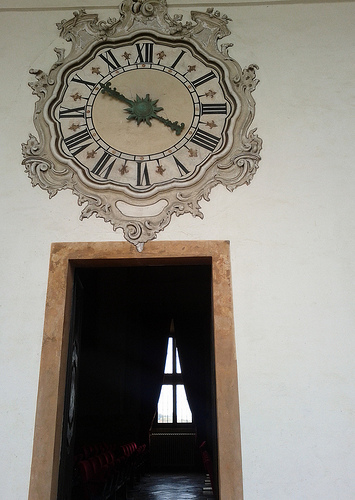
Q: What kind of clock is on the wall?
A: A clock with roman numerals.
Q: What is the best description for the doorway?
A: It is made out of beige marble.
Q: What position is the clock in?
A: Hanging over the doorway.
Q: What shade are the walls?
A: White.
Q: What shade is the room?
A: The inside of the room is dark.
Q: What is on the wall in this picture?
A: A clock.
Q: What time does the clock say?
A: 3:51.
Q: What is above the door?
A: Clock.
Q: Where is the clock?
A: Above the door.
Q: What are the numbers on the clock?
A: Roman numerals.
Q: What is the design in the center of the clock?
A: Sun.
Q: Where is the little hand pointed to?
A: 4.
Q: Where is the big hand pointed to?
A: 10.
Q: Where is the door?
A: Under the clock.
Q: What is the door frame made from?
A: Wood.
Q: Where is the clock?
A: Over the doorway.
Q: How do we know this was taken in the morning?
A: Because it is 9:50 and it's light outside.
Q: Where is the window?
A: In the other room.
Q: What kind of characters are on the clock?
A: Roman numerals.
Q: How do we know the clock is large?
A: It is wider than the doorway.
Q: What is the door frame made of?
A: Wood.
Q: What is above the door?
A: A clock.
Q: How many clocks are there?
A: One.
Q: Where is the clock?
A: On the wall.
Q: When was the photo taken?
A: Daytime.